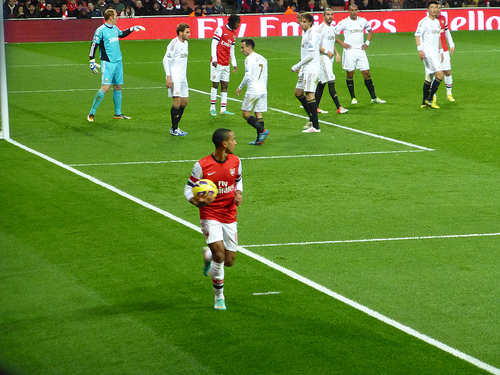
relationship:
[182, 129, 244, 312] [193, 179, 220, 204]
man holding ball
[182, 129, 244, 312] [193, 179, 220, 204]
player holding ball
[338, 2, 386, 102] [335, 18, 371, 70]
male wearing white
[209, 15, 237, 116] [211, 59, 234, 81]
guy wearing white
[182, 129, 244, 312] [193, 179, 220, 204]
player has ball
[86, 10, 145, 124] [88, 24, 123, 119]
goalie wearing blue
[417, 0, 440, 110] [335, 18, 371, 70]
teammate wearing white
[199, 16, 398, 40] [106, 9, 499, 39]
logo on wall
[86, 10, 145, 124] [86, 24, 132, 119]
goalie wearing outfit